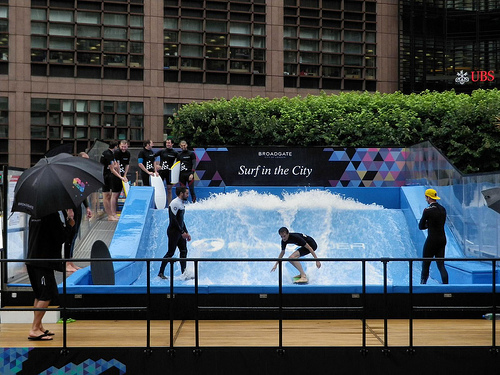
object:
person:
[298, 90, 343, 160]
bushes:
[165, 85, 499, 179]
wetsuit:
[418, 202, 449, 285]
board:
[90, 239, 115, 285]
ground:
[450, 152, 467, 184]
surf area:
[46, 143, 498, 317]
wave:
[203, 180, 385, 251]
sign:
[453, 66, 499, 88]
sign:
[225, 146, 327, 183]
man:
[418, 188, 449, 284]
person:
[137, 138, 159, 185]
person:
[113, 138, 131, 209]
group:
[102, 138, 198, 221]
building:
[0, 0, 499, 170]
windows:
[283, 3, 377, 93]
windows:
[400, 5, 499, 95]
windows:
[165, 2, 265, 87]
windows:
[28, 0, 147, 78]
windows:
[31, 97, 144, 166]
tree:
[167, 90, 499, 175]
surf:
[151, 189, 437, 284]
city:
[0, 0, 500, 374]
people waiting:
[136, 137, 197, 205]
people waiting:
[100, 138, 131, 222]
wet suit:
[160, 196, 191, 276]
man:
[269, 226, 321, 284]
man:
[157, 186, 192, 280]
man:
[175, 140, 197, 203]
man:
[155, 138, 178, 208]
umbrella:
[11, 151, 107, 218]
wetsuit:
[281, 233, 320, 257]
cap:
[424, 188, 440, 199]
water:
[129, 186, 440, 285]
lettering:
[238, 151, 313, 177]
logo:
[455, 70, 469, 85]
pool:
[61, 177, 499, 300]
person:
[24, 209, 75, 341]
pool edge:
[56, 278, 200, 318]